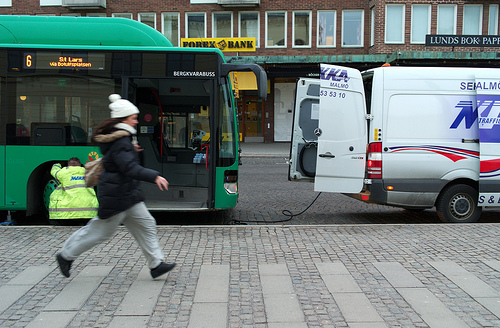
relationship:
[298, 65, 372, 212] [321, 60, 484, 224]
doors on van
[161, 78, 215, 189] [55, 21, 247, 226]
door on bus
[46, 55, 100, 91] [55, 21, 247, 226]
sign on bus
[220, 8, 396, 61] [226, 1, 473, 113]
windows on businesses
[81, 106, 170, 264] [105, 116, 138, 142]
woman wears parka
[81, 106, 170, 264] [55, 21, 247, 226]
woman passes bus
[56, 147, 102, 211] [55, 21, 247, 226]
man looks at bus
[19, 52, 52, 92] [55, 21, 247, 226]
numbers on bus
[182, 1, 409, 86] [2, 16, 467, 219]
building behind vehicles